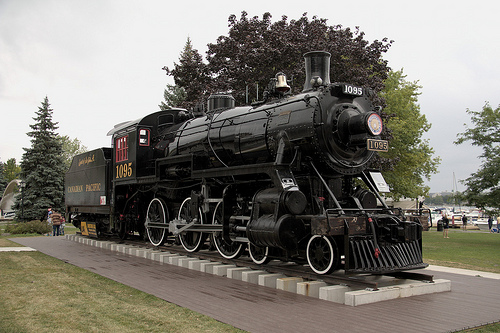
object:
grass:
[0, 261, 168, 331]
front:
[310, 82, 428, 273]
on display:
[58, 49, 442, 295]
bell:
[276, 75, 291, 94]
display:
[66, 233, 452, 306]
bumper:
[351, 235, 429, 272]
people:
[51, 210, 64, 236]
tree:
[15, 90, 71, 223]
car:
[67, 51, 428, 276]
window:
[140, 129, 148, 144]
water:
[209, 281, 273, 304]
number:
[345, 85, 363, 95]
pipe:
[303, 51, 331, 92]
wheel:
[178, 197, 206, 253]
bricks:
[343, 279, 450, 306]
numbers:
[371, 140, 388, 149]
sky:
[0, 0, 500, 153]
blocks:
[10, 230, 500, 333]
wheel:
[213, 200, 248, 259]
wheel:
[306, 234, 337, 275]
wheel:
[248, 243, 269, 264]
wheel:
[145, 198, 167, 247]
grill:
[345, 229, 430, 274]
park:
[0, 0, 500, 333]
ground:
[0, 216, 500, 333]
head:
[54, 210, 59, 213]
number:
[116, 162, 132, 179]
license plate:
[367, 139, 389, 152]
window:
[115, 136, 128, 162]